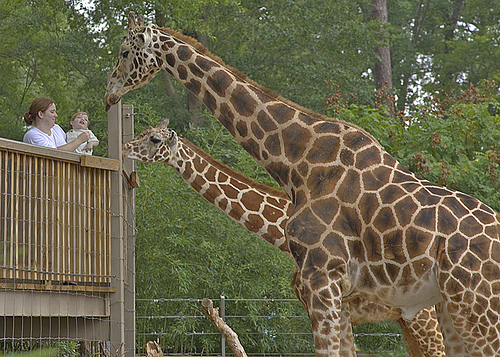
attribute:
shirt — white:
[65, 127, 100, 155]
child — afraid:
[65, 105, 96, 151]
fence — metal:
[134, 287, 416, 350]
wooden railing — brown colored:
[0, 135, 120, 292]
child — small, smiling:
[64, 110, 98, 157]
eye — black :
[122, 45, 139, 60]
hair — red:
[65, 106, 99, 155]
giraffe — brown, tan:
[118, 117, 290, 247]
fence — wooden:
[3, 144, 132, 321]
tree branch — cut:
[198, 297, 247, 355]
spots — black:
[309, 166, 341, 193]